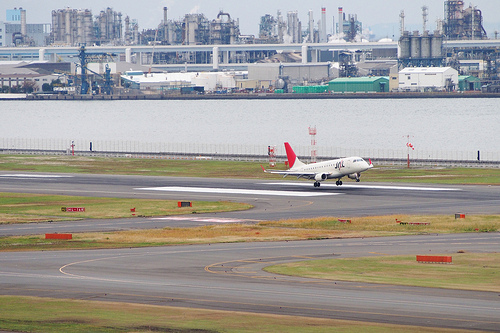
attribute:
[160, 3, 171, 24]
building — tall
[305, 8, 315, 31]
building — tall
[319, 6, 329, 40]
building — tall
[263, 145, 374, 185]
plane — operating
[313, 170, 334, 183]
engines — powerful, jet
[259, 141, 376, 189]
airplane — white, red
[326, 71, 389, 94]
barn — metal, green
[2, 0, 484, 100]
complex — large, industrial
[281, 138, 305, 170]
fin — red, white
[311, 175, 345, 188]
wheels — four, black, airplane, landing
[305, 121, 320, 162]
antenna — orange, white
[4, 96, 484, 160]
river — gray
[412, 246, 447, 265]
retangle — orange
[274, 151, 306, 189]
tail fin — red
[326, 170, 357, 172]
letters — small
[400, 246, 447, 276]
mmarker — red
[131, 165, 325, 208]
rectangle — white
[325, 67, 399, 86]
building — green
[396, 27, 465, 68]
batteries — large, distant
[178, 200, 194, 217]
marker — black, red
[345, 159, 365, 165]
windows — dark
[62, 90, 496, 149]
river — calm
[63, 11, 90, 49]
building — tall, distant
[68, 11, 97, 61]
building — distant, tall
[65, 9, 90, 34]
building — tall, distant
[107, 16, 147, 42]
building — tall, distant